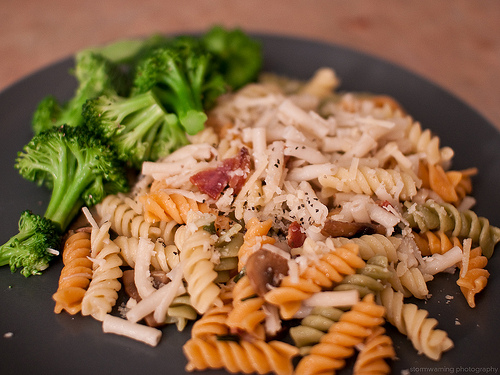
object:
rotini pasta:
[167, 211, 231, 313]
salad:
[117, 57, 407, 282]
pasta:
[184, 125, 416, 310]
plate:
[1, 11, 497, 371]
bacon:
[321, 219, 370, 234]